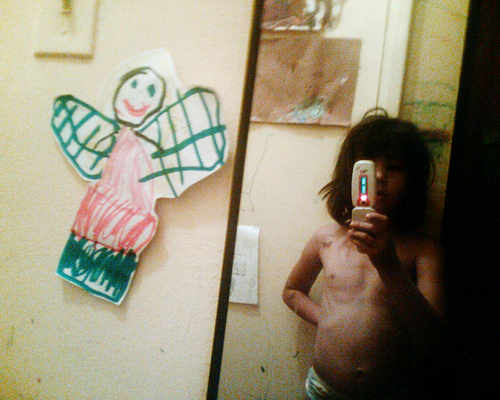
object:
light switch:
[32, 0, 98, 59]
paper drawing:
[49, 48, 228, 306]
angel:
[50, 47, 230, 305]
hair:
[317, 107, 437, 236]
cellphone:
[351, 159, 377, 254]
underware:
[303, 367, 343, 400]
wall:
[0, 0, 253, 400]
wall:
[214, 0, 472, 400]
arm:
[282, 236, 323, 325]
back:
[318, 275, 325, 299]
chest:
[337, 247, 370, 273]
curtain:
[399, 1, 468, 243]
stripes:
[402, 100, 452, 115]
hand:
[347, 212, 394, 258]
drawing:
[50, 67, 225, 303]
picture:
[0, 0, 499, 400]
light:
[361, 176, 367, 194]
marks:
[435, 121, 453, 152]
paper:
[250, 0, 413, 127]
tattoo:
[322, 241, 333, 249]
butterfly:
[322, 241, 332, 249]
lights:
[360, 194, 367, 201]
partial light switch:
[58, 0, 76, 18]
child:
[282, 115, 447, 399]